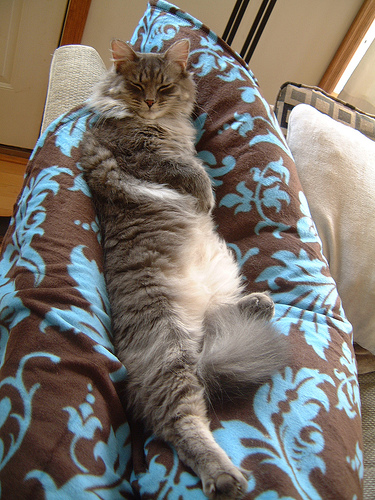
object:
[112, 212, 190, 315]
fur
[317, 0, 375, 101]
frame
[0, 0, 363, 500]
blanket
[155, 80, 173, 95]
eye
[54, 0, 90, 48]
wood trim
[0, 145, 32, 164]
wood trim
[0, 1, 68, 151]
door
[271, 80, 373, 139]
pillows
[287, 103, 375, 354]
pillows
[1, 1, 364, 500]
pillows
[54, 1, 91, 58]
frame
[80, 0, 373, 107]
wall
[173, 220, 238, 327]
fur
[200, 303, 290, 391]
tail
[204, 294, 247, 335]
cat's leg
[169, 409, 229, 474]
cat's leg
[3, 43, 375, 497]
couch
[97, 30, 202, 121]
head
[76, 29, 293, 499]
cat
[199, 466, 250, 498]
paw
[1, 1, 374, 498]
inside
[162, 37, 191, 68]
ear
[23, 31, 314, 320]
scene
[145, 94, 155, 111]
nose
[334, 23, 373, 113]
window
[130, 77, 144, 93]
eye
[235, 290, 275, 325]
paw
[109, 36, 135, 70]
ear